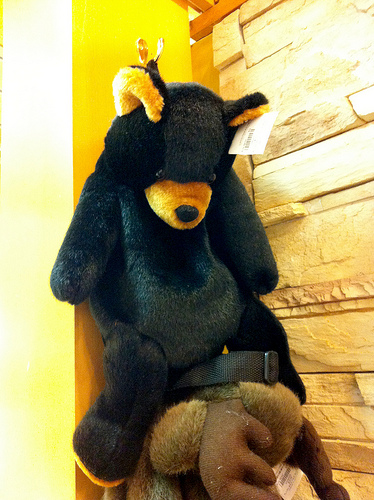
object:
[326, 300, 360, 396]
brick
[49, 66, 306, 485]
teddy bear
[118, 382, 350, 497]
moose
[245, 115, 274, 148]
white tag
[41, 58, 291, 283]
teddy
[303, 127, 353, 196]
brick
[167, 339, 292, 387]
strap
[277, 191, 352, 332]
brick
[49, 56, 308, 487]
bear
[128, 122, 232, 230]
face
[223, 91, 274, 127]
ear